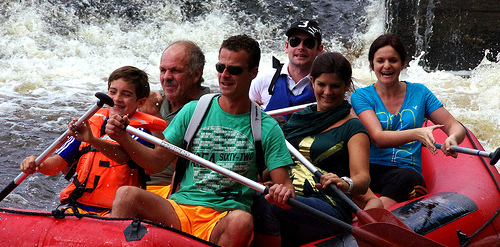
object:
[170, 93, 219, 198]
strap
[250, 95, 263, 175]
strap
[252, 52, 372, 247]
woman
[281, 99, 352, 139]
green scarf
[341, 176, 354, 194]
silver watch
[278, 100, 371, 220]
shirt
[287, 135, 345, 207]
gold leaf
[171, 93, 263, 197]
straps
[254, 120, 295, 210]
shoulder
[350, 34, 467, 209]
woman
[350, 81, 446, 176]
blue shirt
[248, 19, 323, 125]
man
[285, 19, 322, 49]
hat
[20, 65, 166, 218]
boy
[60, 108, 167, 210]
life vest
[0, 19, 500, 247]
group of people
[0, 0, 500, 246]
rafting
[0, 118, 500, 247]
red raft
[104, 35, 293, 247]
man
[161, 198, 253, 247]
yellow shorts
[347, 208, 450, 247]
bottoms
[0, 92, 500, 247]
paddles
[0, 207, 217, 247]
front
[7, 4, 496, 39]
waterfall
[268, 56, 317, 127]
life jacket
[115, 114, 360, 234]
pole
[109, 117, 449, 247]
paddle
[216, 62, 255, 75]
sunglasses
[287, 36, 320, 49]
sunglasses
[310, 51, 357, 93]
brown hair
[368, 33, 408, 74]
brown hair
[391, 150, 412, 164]
white writing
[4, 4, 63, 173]
water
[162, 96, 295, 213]
shirt